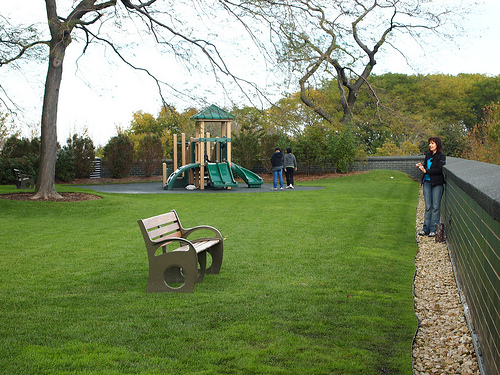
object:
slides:
[163, 160, 265, 190]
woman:
[416, 136, 448, 238]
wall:
[350, 154, 495, 374]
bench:
[138, 208, 224, 298]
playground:
[192, 102, 237, 121]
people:
[269, 148, 300, 190]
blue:
[423, 159, 440, 185]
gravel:
[3, 190, 110, 204]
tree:
[1, 1, 191, 204]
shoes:
[418, 226, 443, 239]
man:
[270, 147, 286, 192]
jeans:
[270, 168, 287, 190]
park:
[3, 4, 498, 371]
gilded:
[161, 118, 234, 189]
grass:
[2, 169, 415, 370]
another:
[11, 168, 34, 191]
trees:
[225, 0, 426, 191]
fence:
[58, 152, 437, 191]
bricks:
[480, 211, 499, 300]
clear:
[73, 59, 143, 143]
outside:
[1, 0, 500, 375]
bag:
[435, 221, 445, 243]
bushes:
[5, 133, 168, 185]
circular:
[1, 185, 104, 208]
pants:
[285, 167, 296, 188]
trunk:
[36, 44, 65, 207]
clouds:
[2, 1, 498, 143]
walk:
[105, 180, 309, 199]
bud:
[5, 182, 98, 207]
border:
[412, 173, 475, 372]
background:
[4, 1, 490, 148]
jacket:
[419, 153, 450, 186]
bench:
[7, 162, 38, 188]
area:
[83, 155, 355, 205]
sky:
[0, 1, 495, 151]